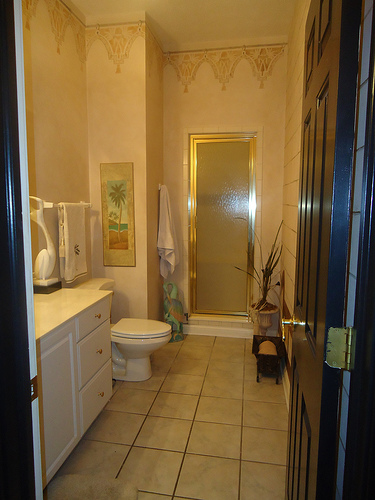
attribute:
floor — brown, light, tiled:
[169, 393, 252, 450]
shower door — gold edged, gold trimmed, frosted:
[196, 138, 249, 310]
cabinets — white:
[68, 310, 111, 420]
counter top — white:
[52, 294, 86, 312]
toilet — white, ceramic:
[115, 312, 170, 364]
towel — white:
[61, 201, 91, 283]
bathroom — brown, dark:
[17, 6, 370, 493]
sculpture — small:
[163, 275, 190, 323]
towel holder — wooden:
[48, 198, 94, 210]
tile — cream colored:
[128, 410, 176, 459]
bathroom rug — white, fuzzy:
[50, 475, 140, 500]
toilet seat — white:
[124, 321, 166, 335]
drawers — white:
[73, 332, 113, 403]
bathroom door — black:
[300, 15, 352, 348]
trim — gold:
[187, 132, 259, 144]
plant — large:
[244, 233, 281, 302]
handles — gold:
[95, 310, 104, 324]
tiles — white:
[173, 357, 239, 398]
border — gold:
[162, 53, 278, 78]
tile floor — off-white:
[122, 445, 156, 477]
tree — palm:
[104, 180, 129, 211]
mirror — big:
[203, 151, 237, 262]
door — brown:
[302, 17, 357, 229]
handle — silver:
[278, 316, 300, 345]